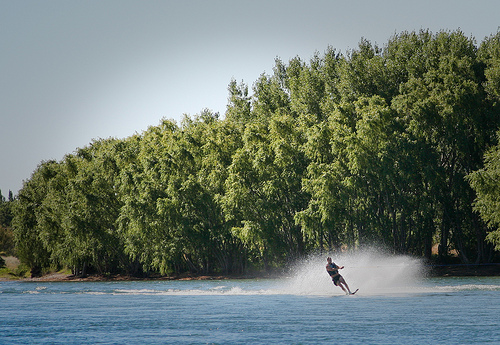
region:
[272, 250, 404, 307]
Person sking on water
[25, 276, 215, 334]
Blue water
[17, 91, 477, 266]
Shoreline of trees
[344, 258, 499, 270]
Cable the skier holds on to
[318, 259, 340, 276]
Life vest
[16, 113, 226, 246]
Green leaves on the trees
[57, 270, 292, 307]
White waves on the water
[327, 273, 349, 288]
Black shorts on the skier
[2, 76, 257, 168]
Clear sky over the trees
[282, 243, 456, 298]
Water spray from the skier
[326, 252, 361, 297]
a person waterskiing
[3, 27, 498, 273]
some trees growing beside the lake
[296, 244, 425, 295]
the spray of water caused by the waterskis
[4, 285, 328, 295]
the wake caused by the waterskiier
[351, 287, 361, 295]
the front of a waterski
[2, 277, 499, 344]
the water in the lake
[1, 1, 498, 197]
the sky above the trees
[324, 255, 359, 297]
a man on waterskis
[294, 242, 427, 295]
water splashing up behind a waterskiier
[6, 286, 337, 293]
a trail through the water made by the waterskiier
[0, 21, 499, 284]
A lot of trees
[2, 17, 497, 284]
A big forest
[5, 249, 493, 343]
A big mass of water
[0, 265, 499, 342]
This is a big lake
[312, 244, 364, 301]
This is a person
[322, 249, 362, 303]
This is a man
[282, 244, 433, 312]
This is a man splashing water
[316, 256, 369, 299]
This is water skating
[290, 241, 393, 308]
This is a man skating in water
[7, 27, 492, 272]
Thse are all trees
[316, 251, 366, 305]
Person is water skiing.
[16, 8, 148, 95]
The sky is grey.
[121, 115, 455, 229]
The trees are green.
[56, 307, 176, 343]
The water is blue.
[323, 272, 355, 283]
Person is wearing shorts.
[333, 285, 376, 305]
Part of the ski is sticking up.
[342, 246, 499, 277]
Person holding onto a rope.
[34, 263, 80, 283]
Dirt in front of the tree.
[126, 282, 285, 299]
The water is white.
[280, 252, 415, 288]
Water in the air.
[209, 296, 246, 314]
ripple in the water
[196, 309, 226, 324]
ripple in the water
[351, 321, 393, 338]
ripple in the water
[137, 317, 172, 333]
ripple in the water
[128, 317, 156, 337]
ripple in the water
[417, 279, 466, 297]
ripple in the water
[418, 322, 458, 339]
ripple in the water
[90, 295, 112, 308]
ripple in the water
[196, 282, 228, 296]
ripple in the water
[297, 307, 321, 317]
ripple in the water